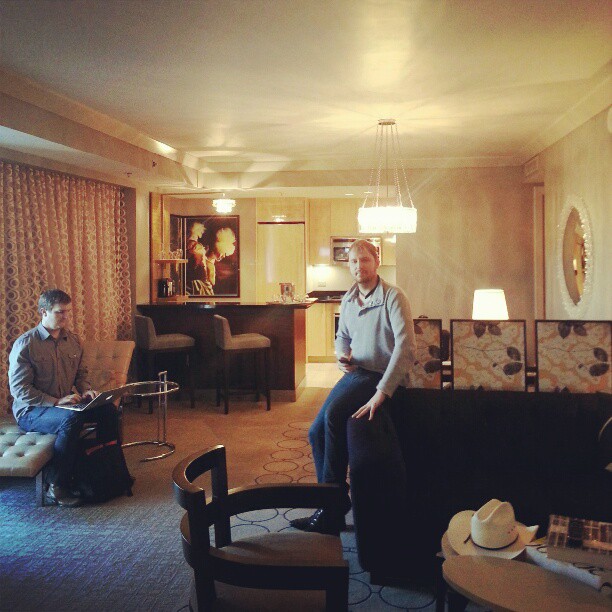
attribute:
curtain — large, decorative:
[5, 157, 137, 411]